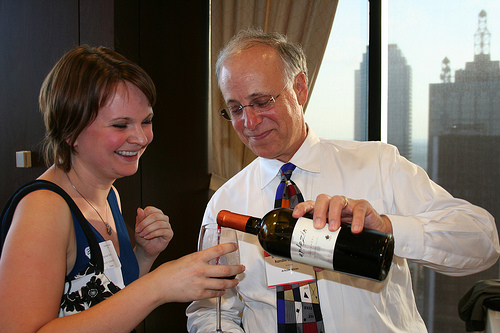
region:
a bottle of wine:
[209, 204, 399, 279]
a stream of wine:
[212, 217, 222, 274]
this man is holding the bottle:
[172, 12, 497, 332]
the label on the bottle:
[288, 210, 343, 274]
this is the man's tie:
[270, 168, 319, 331]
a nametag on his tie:
[250, 242, 327, 293]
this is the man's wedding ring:
[337, 190, 351, 212]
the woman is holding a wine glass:
[14, 33, 249, 332]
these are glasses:
[213, 87, 290, 128]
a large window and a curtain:
[204, 0, 498, 297]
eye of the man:
[250, 93, 275, 111]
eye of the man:
[227, 100, 246, 117]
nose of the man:
[238, 110, 263, 127]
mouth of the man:
[250, 133, 277, 145]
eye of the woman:
[105, 115, 129, 131]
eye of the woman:
[138, 118, 154, 129]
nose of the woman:
[120, 128, 154, 143]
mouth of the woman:
[110, 142, 146, 157]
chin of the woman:
[116, 168, 143, 181]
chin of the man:
[252, 144, 281, 158]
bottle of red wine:
[200, 199, 387, 281]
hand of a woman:
[122, 198, 181, 260]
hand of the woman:
[182, 239, 239, 296]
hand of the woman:
[287, 194, 377, 231]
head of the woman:
[32, 47, 171, 199]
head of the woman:
[215, 5, 320, 160]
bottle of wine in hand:
[184, 183, 393, 300]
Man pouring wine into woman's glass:
[0, 30, 497, 329]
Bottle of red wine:
[217, 208, 393, 281]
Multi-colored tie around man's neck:
[271, 161, 325, 331]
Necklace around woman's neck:
[68, 174, 117, 238]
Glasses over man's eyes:
[221, 87, 277, 119]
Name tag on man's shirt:
[261, 242, 318, 289]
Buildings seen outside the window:
[356, 9, 496, 329]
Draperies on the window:
[206, 0, 339, 190]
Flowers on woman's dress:
[68, 275, 119, 312]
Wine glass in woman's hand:
[198, 219, 240, 330]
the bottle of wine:
[215, 205, 393, 278]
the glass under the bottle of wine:
[197, 223, 239, 331]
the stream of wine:
[214, 221, 221, 263]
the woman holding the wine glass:
[1, 43, 244, 332]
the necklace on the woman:
[65, 163, 112, 235]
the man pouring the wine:
[185, 25, 498, 331]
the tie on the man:
[274, 163, 325, 331]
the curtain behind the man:
[206, 0, 338, 199]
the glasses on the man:
[218, 75, 290, 120]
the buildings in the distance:
[352, 8, 499, 331]